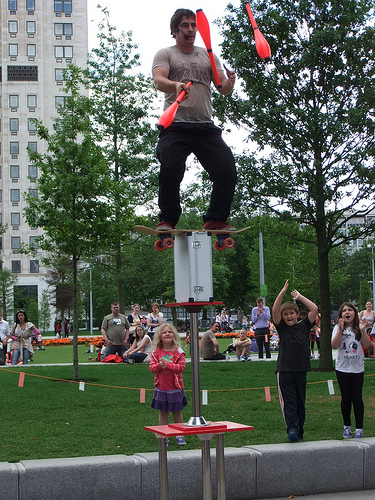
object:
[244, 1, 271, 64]
juggling pin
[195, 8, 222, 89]
juggling pin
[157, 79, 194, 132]
juggling pin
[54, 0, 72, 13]
window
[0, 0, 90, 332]
building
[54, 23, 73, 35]
window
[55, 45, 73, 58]
window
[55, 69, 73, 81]
window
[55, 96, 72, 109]
window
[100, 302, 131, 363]
man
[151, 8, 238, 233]
juggler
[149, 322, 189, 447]
girl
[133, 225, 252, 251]
skateboard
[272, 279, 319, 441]
boy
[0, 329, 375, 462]
grass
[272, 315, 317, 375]
shirt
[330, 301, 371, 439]
girl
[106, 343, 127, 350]
pockets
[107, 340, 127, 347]
hands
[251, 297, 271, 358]
man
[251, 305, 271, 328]
shirt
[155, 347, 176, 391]
shirt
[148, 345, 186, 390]
jacket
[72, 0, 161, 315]
tree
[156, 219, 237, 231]
shoes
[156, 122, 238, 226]
pants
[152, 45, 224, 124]
shirt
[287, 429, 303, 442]
shoes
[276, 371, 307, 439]
pants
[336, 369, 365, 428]
leggings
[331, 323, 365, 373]
shirt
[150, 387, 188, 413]
skirt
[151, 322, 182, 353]
hair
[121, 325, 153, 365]
woman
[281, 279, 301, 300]
hands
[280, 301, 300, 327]
head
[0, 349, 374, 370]
sidewalk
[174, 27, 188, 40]
microphone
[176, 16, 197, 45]
face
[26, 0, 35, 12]
window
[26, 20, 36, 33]
window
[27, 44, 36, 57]
window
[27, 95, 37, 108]
window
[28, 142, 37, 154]
window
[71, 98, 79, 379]
trunk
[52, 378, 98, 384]
dirt